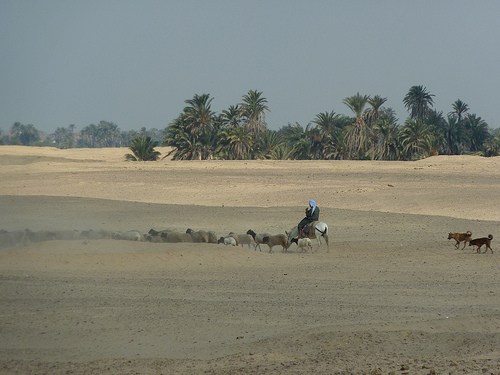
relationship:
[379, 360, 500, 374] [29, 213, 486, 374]
stones in dust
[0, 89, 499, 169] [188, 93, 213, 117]
palm trees has leaves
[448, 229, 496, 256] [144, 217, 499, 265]
dogs following pack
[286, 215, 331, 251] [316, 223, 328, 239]
donkey has tail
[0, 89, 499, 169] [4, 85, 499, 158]
palm trees in a line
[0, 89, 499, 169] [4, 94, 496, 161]
palm trees on background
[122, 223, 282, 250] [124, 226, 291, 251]
dust surrounding sheep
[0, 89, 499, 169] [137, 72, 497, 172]
palm trees in cluster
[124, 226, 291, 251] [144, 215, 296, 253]
sheep in herd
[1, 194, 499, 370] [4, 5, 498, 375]
oasis in desert